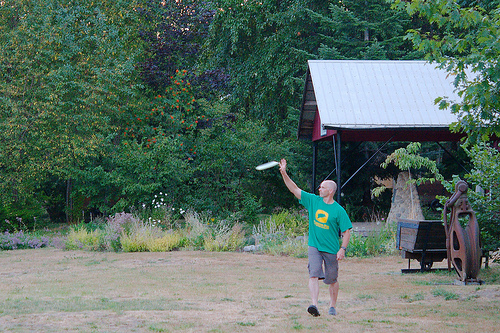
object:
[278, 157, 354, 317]
man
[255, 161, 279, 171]
frisbee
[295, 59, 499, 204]
barn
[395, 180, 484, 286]
equipment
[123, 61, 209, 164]
red flowers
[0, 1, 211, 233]
tree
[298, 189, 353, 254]
green shirt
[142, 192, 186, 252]
bush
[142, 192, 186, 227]
white flowers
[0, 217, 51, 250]
bush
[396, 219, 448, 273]
cart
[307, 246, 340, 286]
shorts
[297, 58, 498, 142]
roof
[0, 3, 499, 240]
background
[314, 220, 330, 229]
yellow letters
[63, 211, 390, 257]
grass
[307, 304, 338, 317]
shoes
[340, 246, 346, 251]
watch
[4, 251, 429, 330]
grass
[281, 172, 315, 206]
arm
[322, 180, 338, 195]
shaved head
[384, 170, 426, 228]
object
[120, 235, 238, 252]
orange leaves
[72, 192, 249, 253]
bushes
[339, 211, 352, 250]
left arm